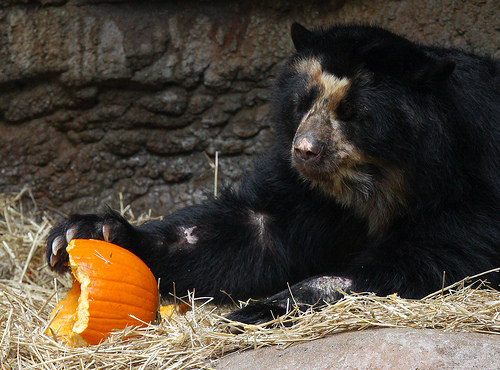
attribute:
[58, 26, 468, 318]
bear — black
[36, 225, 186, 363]
pumpkin shell — orange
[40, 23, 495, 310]
bear — black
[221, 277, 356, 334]
spot — gray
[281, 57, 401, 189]
face — tan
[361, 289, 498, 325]
hay — yellow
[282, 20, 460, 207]
face — white, brown, bear's